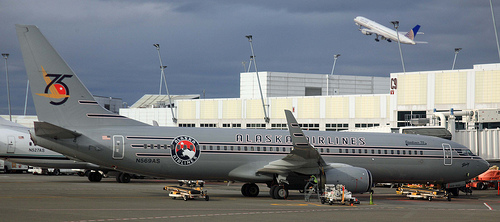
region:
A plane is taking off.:
[351, 9, 428, 53]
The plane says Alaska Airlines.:
[234, 130, 373, 149]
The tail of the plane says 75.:
[33, 59, 80, 108]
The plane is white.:
[347, 8, 432, 52]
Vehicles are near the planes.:
[164, 174, 215, 204]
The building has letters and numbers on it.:
[388, 71, 398, 98]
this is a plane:
[15, 13, 497, 213]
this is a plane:
[345, 10, 453, 67]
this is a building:
[383, 51, 498, 168]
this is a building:
[233, 68, 398, 142]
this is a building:
[103, 76, 237, 136]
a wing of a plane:
[255, 92, 332, 169]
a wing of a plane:
[350, 22, 387, 52]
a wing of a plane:
[16, 11, 117, 140]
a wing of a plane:
[400, 23, 428, 51]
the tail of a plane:
[6, 17, 110, 139]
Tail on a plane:
[9, 20, 114, 185]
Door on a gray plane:
[100, 128, 130, 160]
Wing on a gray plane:
[265, 105, 337, 198]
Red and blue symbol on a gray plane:
[168, 130, 204, 170]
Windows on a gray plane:
[136, 139, 173, 154]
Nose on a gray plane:
[454, 141, 490, 181]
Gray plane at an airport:
[2, 19, 499, 213]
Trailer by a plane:
[155, 167, 211, 204]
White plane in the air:
[344, 8, 434, 55]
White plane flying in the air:
[346, 8, 426, 54]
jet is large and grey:
[14, 24, 489, 198]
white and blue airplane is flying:
[355, 15, 425, 47]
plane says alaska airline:
[235, 132, 366, 144]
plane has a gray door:
[440, 141, 453, 166]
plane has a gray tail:
[11, 25, 152, 172]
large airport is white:
[119, 69, 497, 159]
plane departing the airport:
[352, 5, 432, 52]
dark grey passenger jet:
[12, 21, 487, 188]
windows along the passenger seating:
[144, 141, 425, 159]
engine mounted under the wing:
[297, 155, 373, 192]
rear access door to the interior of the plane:
[109, 133, 128, 158]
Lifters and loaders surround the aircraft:
[158, 174, 472, 203]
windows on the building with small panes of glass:
[179, 123, 394, 135]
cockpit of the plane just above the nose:
[450, 136, 489, 179]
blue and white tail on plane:
[403, 19, 426, 36]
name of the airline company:
[229, 130, 376, 146]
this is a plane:
[15, 20, 497, 219]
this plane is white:
[349, 6, 436, 70]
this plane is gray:
[10, 17, 495, 212]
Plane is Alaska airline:
[11, 20, 492, 200]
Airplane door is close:
[111, 132, 125, 159]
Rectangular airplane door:
[441, 140, 453, 166]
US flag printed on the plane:
[99, 133, 112, 140]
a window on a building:
[245, 121, 252, 131]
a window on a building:
[210, 121, 215, 124]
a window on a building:
[230, 121, 235, 127]